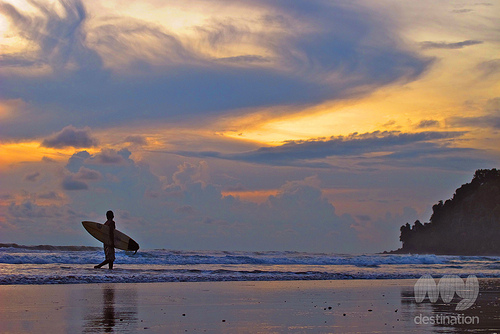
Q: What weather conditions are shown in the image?
A: It is cloudy.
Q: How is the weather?
A: It is cloudy.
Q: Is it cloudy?
A: Yes, it is cloudy.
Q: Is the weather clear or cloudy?
A: It is cloudy.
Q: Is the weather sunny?
A: No, it is cloudy.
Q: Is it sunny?
A: No, it is cloudy.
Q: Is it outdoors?
A: Yes, it is outdoors.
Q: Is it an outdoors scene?
A: Yes, it is outdoors.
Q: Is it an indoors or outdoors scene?
A: It is outdoors.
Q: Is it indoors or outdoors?
A: It is outdoors.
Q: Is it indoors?
A: No, it is outdoors.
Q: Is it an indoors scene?
A: No, it is outdoors.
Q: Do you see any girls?
A: No, there are no girls.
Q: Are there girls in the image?
A: No, there are no girls.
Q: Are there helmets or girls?
A: No, there are no girls or helmets.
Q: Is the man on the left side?
A: Yes, the man is on the left of the image.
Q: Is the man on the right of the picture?
A: No, the man is on the left of the image.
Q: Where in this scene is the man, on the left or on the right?
A: The man is on the left of the image.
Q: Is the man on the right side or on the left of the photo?
A: The man is on the left of the image.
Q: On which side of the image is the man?
A: The man is on the left of the image.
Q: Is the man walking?
A: Yes, the man is walking.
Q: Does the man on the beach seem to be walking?
A: Yes, the man is walking.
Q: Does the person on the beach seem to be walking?
A: Yes, the man is walking.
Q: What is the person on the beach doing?
A: The man is walking.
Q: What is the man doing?
A: The man is walking.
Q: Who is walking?
A: The man is walking.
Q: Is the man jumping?
A: No, the man is walking.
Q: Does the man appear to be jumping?
A: No, the man is walking.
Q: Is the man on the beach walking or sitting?
A: The man is walking.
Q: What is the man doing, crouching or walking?
A: The man is walking.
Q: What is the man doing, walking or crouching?
A: The man is walking.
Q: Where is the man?
A: The man is on the beach.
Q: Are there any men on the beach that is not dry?
A: Yes, there is a man on the beach.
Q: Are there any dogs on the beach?
A: No, there is a man on the beach.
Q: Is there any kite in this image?
A: No, there are no kites.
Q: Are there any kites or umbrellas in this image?
A: No, there are no kites or umbrellas.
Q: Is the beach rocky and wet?
A: Yes, the beach is rocky and wet.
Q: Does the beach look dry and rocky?
A: No, the beach is rocky but wet.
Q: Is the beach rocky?
A: Yes, the beach is rocky.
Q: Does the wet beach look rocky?
A: Yes, the beach is rocky.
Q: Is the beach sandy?
A: No, the beach is rocky.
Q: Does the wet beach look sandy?
A: No, the beach is rocky.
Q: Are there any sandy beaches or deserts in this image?
A: No, there is a beach but it is rocky.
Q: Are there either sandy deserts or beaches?
A: No, there is a beach but it is rocky.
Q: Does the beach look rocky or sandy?
A: The beach is rocky.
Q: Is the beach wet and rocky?
A: Yes, the beach is wet and rocky.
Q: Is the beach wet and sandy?
A: No, the beach is wet but rocky.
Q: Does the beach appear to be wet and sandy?
A: No, the beach is wet but rocky.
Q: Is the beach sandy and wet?
A: No, the beach is wet but rocky.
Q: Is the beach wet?
A: Yes, the beach is wet.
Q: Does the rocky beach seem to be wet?
A: Yes, the beach is wet.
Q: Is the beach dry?
A: No, the beach is wet.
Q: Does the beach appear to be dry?
A: No, the beach is wet.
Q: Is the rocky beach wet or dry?
A: The beach is wet.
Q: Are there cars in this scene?
A: No, there are no cars.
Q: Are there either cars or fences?
A: No, there are no cars or fences.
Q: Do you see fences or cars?
A: No, there are no cars or fences.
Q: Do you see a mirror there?
A: No, there are no mirrors.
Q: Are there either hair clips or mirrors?
A: No, there are no mirrors or hair clips.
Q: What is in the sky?
A: The clouds are in the sky.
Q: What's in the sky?
A: The clouds are in the sky.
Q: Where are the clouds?
A: The clouds are in the sky.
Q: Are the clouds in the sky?
A: Yes, the clouds are in the sky.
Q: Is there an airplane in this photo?
A: No, there are no airplanes.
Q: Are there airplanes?
A: No, there are no airplanes.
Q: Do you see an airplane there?
A: No, there are no airplanes.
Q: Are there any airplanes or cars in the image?
A: No, there are no airplanes or cars.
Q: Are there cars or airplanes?
A: No, there are no airplanes or cars.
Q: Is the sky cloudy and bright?
A: Yes, the sky is cloudy and bright.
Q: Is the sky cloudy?
A: Yes, the sky is cloudy.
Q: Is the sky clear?
A: No, the sky is cloudy.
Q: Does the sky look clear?
A: No, the sky is cloudy.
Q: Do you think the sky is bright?
A: Yes, the sky is bright.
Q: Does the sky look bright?
A: Yes, the sky is bright.